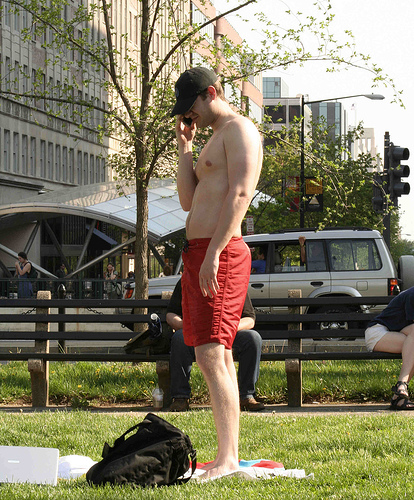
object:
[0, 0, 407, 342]
trees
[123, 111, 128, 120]
leaves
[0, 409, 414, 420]
path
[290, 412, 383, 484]
grass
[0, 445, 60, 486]
laptop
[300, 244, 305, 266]
arm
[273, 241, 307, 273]
window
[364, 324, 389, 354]
white shorts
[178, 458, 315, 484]
towel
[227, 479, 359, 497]
grass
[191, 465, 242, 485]
feet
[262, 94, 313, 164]
building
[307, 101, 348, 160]
building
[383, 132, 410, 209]
stoplight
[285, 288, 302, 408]
support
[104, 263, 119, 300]
woman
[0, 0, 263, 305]
building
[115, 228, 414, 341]
suv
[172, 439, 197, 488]
strap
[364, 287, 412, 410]
person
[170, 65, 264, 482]
man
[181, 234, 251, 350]
shorts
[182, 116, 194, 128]
cellphone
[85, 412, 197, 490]
bag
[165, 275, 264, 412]
man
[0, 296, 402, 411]
bench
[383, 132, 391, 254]
pole